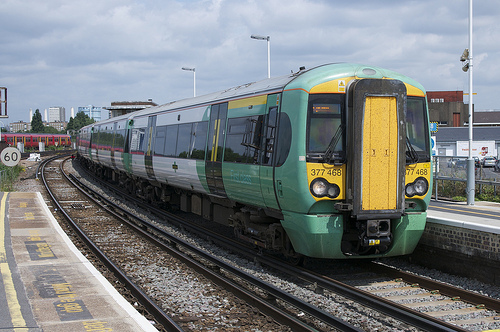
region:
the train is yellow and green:
[273, 49, 450, 294]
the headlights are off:
[270, 160, 448, 215]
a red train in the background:
[0, 109, 76, 159]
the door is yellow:
[350, 83, 405, 215]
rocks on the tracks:
[388, 272, 483, 317]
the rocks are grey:
[376, 264, 476, 322]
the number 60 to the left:
[2, 132, 40, 185]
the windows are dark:
[81, 122, 266, 166]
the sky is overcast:
[17, 6, 350, 116]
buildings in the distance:
[4, 92, 108, 131]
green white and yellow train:
[158, 96, 429, 275]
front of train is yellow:
[316, 79, 455, 259]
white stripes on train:
[59, 117, 174, 174]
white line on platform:
[9, 175, 119, 330]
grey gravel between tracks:
[59, 183, 232, 328]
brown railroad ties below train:
[57, 185, 251, 330]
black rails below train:
[37, 150, 280, 325]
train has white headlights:
[312, 174, 441, 202]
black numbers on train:
[300, 166, 427, 190]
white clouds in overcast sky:
[110, 28, 277, 86]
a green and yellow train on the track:
[52, 64, 434, 259]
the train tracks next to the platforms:
[41, 143, 484, 330]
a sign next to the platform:
[0, 147, 27, 187]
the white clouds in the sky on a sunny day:
[5, 0, 497, 85]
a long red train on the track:
[3, 130, 73, 147]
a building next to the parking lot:
[437, 124, 499, 159]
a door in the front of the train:
[349, 83, 402, 217]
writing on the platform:
[19, 234, 95, 326]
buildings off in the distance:
[46, 101, 148, 121]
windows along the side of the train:
[91, 121, 279, 168]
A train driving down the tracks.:
[76, 61, 433, 258]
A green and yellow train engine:
[284, 59, 442, 262]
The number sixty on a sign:
[0, 149, 20, 169]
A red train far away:
[3, 124, 70, 151]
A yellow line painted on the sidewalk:
[0, 182, 20, 327]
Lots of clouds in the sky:
[44, 9, 458, 68]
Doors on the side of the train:
[192, 82, 246, 195]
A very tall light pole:
[242, 27, 285, 74]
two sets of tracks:
[148, 280, 485, 325]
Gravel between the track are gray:
[168, 285, 226, 318]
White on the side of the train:
[149, 153, 206, 190]